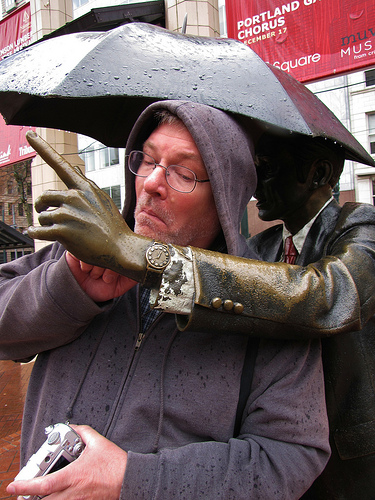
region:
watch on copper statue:
[137, 237, 177, 297]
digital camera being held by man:
[7, 412, 109, 499]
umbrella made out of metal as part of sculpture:
[13, 29, 366, 203]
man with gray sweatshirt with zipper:
[9, 63, 364, 466]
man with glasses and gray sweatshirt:
[86, 98, 264, 255]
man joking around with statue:
[13, 68, 345, 479]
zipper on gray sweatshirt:
[116, 323, 155, 408]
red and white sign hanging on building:
[224, 9, 371, 49]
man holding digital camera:
[11, 368, 201, 490]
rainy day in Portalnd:
[10, 39, 352, 431]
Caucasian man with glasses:
[69, 92, 309, 478]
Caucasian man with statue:
[6, 16, 374, 410]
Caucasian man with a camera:
[20, 360, 139, 497]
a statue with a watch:
[56, 122, 373, 409]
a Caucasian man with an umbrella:
[25, 60, 346, 418]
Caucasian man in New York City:
[30, 18, 374, 281]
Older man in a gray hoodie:
[28, 27, 368, 468]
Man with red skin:
[4, 110, 373, 403]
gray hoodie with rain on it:
[17, 129, 326, 498]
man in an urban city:
[41, 17, 369, 454]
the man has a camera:
[8, 420, 79, 496]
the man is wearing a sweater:
[6, 102, 332, 494]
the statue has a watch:
[144, 241, 171, 289]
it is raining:
[0, 1, 373, 497]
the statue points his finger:
[27, 129, 85, 189]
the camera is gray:
[11, 423, 80, 496]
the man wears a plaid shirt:
[135, 280, 168, 329]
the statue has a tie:
[284, 239, 295, 265]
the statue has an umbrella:
[0, 22, 373, 166]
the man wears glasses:
[125, 150, 213, 192]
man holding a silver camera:
[9, 124, 295, 496]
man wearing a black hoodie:
[14, 119, 307, 496]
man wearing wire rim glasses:
[104, 151, 237, 196]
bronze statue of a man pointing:
[15, 117, 352, 362]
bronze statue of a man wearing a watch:
[12, 122, 353, 315]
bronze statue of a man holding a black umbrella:
[0, 32, 335, 227]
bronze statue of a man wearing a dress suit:
[129, 184, 355, 359]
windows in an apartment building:
[41, 140, 133, 244]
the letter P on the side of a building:
[221, 3, 286, 43]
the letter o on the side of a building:
[225, 2, 305, 49]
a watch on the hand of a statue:
[147, 241, 167, 275]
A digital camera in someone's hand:
[8, 421, 84, 498]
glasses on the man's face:
[124, 147, 203, 194]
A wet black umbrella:
[0, 21, 373, 176]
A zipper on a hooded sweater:
[132, 320, 144, 353]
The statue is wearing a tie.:
[274, 234, 304, 267]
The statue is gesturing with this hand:
[22, 127, 127, 267]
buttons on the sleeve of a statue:
[207, 294, 247, 313]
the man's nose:
[143, 164, 167, 199]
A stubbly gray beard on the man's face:
[133, 193, 209, 245]